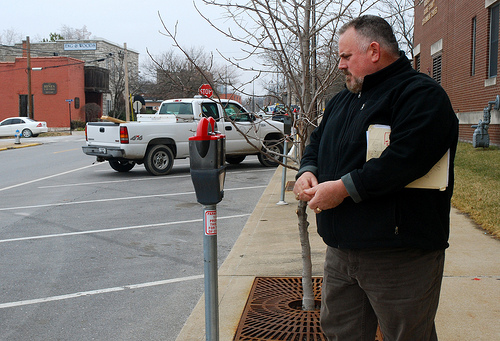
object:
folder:
[351, 115, 469, 197]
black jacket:
[296, 51, 462, 252]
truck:
[76, 93, 295, 180]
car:
[0, 116, 50, 137]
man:
[277, 20, 480, 311]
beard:
[345, 78, 370, 98]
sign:
[131, 98, 142, 113]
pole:
[171, 102, 261, 339]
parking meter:
[188, 120, 226, 340]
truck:
[81, 97, 285, 173]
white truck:
[91, 84, 281, 158]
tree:
[150, 2, 420, 329]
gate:
[228, 270, 411, 340]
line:
[0, 273, 207, 310]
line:
[0, 210, 250, 246]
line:
[0, 182, 268, 213]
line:
[16, 165, 278, 192]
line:
[0, 159, 107, 194]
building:
[2, 44, 96, 132]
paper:
[446, 126, 452, 186]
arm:
[342, 81, 455, 206]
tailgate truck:
[70, 122, 133, 155]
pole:
[281, 132, 288, 200]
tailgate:
[84, 120, 125, 150]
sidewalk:
[168, 120, 493, 339]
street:
[0, 106, 284, 339]